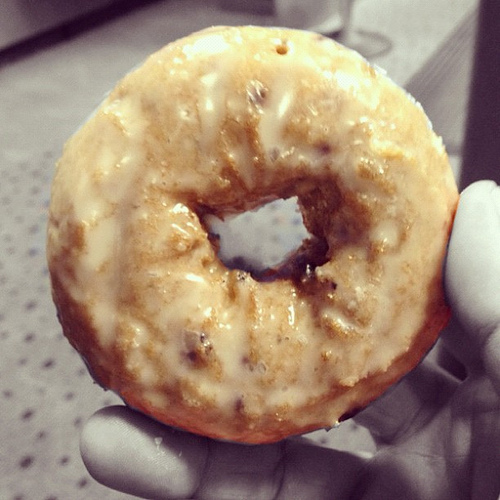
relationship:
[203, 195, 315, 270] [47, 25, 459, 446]
hole in donut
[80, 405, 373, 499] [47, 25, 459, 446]
finger holding donut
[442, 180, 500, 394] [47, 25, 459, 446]
thumb holding donut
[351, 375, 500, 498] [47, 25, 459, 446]
palm under donut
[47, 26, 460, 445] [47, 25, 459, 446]
glaze on donut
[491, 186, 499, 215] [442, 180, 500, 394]
fingernail on thumb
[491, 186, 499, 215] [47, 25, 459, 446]
fingernail on donut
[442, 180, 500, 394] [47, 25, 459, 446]
thumb on donut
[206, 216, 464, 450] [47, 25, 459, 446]
middle finger under donut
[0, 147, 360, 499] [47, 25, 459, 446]
polka dots are behind donut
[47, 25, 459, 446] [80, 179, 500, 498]
donut in hand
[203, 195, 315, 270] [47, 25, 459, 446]
hole in center of donut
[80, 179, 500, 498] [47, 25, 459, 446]
hand holding donut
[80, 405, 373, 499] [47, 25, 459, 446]
finger on donut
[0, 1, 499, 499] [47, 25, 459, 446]
background behind donut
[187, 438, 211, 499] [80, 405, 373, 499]
crease in finger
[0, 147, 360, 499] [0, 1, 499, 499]
polka dots are in background